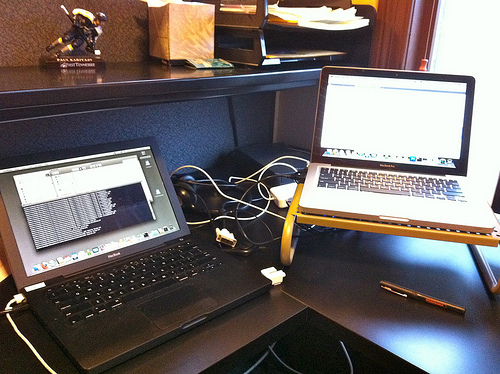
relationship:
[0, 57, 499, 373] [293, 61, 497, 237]
station for computer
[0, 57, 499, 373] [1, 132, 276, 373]
station for computer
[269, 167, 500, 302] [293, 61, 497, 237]
table holds computer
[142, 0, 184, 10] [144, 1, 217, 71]
tissues in box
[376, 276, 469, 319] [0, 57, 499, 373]
pen on station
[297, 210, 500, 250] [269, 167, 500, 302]
edge of table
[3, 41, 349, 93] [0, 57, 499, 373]
top of station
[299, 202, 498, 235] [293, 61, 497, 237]
edge of computer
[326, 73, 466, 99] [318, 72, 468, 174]
part of screen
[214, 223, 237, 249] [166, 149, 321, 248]
part of cable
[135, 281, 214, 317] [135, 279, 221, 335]
part of mouse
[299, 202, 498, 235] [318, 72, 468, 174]
edge of screen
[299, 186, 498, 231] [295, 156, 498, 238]
part of board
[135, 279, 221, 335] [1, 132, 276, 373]
mouse of computer